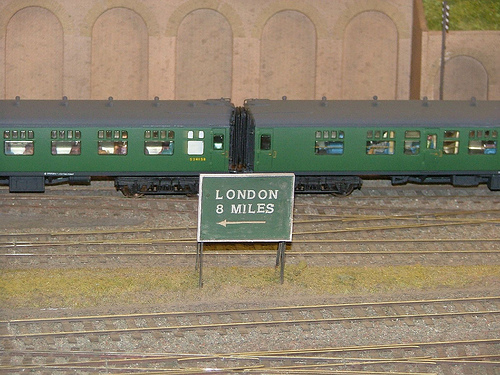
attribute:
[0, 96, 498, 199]
train — green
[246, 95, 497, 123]
roof — gray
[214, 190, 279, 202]
lettering — white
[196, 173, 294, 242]
sign — green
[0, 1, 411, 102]
wall — brick